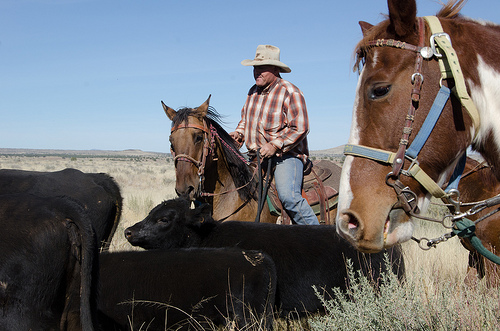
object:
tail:
[49, 196, 96, 331]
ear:
[196, 94, 211, 122]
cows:
[122, 185, 395, 320]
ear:
[386, 0, 417, 39]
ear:
[358, 20, 374, 37]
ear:
[161, 100, 177, 121]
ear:
[194, 203, 212, 227]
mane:
[172, 105, 258, 202]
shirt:
[234, 77, 310, 165]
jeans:
[274, 157, 322, 225]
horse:
[334, 0, 500, 257]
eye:
[196, 136, 204, 144]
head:
[334, 0, 476, 254]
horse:
[160, 93, 406, 286]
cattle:
[0, 194, 97, 331]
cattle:
[0, 166, 125, 331]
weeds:
[306, 251, 500, 331]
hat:
[240, 44, 292, 74]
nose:
[335, 206, 367, 245]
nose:
[175, 184, 196, 198]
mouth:
[355, 201, 415, 254]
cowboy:
[226, 44, 321, 226]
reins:
[254, 147, 271, 222]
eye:
[369, 84, 392, 99]